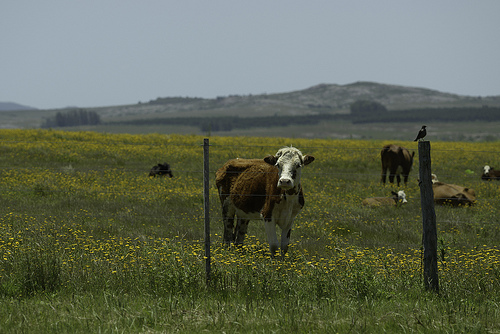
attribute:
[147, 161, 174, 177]
cow — black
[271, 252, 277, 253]
flowers — yellow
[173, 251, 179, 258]
flowers — yellow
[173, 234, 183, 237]
flowers — yellow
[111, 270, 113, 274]
flowers — yellow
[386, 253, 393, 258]
flowers — yellow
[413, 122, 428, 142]
bird — black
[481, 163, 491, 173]
face — white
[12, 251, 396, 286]
wild flowers — yellow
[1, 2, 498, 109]
sky — blue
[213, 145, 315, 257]
cow — red, white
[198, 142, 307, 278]
cow — brown and white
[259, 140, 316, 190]
head — white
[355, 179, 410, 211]
cow — brown, white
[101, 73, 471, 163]
mountains — distant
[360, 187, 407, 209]
cow — baby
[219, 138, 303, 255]
cow — brown and white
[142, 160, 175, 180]
cow — black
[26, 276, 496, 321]
grass — green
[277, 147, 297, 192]
face — white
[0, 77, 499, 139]
hills — dry, grey, rolling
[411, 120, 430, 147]
bird — black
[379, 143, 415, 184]
cow — brown